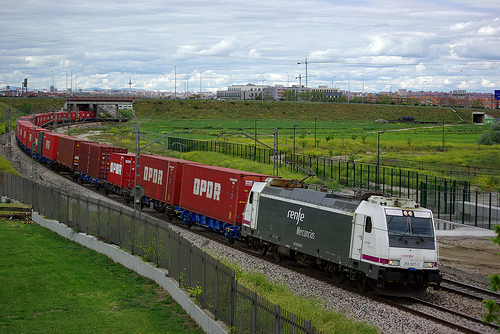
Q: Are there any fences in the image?
A: Yes, there is a fence.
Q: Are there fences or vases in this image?
A: Yes, there is a fence.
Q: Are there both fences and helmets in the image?
A: No, there is a fence but no helmets.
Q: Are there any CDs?
A: No, there are no cds.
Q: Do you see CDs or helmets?
A: No, there are no CDs or helmets.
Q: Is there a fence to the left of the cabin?
A: Yes, there is a fence to the left of the cabin.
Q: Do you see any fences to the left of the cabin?
A: Yes, there is a fence to the left of the cabin.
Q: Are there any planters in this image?
A: No, there are no planters.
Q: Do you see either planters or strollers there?
A: No, there are no planters or strollers.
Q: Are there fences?
A: Yes, there is a fence.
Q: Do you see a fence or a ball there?
A: Yes, there is a fence.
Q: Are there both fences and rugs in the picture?
A: No, there is a fence but no rugs.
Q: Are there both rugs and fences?
A: No, there is a fence but no rugs.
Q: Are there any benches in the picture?
A: No, there are no benches.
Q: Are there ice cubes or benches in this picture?
A: No, there are no benches or ice cubes.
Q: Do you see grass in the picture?
A: Yes, there is grass.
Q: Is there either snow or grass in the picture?
A: Yes, there is grass.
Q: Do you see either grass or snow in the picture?
A: Yes, there is grass.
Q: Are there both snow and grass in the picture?
A: No, there is grass but no snow.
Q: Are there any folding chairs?
A: No, there are no folding chairs.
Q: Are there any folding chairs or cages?
A: No, there are no folding chairs or cages.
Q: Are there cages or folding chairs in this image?
A: No, there are no folding chairs or cages.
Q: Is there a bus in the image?
A: No, there are no buses.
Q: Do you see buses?
A: No, there are no buses.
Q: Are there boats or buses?
A: No, there are no buses or boats.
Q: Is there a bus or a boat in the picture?
A: No, there are no buses or boats.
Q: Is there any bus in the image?
A: No, there are no buses.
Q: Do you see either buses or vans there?
A: No, there are no buses or vans.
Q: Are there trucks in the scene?
A: No, there are no trucks.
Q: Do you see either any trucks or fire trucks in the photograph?
A: No, there are no trucks or fire trucks.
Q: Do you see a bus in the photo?
A: No, there are no buses.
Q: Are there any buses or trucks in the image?
A: No, there are no buses or trucks.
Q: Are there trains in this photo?
A: Yes, there is a train.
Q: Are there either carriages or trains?
A: Yes, there is a train.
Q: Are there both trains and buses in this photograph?
A: No, there is a train but no buses.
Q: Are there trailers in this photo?
A: No, there are no trailers.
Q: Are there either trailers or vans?
A: No, there are no trailers or vans.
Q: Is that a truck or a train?
A: That is a train.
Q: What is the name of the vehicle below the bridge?
A: The vehicle is a train.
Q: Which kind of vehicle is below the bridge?
A: The vehicle is a train.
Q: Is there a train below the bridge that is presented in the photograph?
A: Yes, there is a train below the bridge.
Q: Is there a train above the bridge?
A: No, the train is below the bridge.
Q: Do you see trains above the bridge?
A: No, the train is below the bridge.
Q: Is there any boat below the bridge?
A: No, there is a train below the bridge.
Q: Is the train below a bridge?
A: Yes, the train is below a bridge.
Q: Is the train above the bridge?
A: No, the train is below the bridge.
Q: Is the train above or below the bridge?
A: The train is below the bridge.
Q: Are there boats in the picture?
A: No, there are no boats.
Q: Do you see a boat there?
A: No, there are no boats.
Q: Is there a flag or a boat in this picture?
A: No, there are no boats or flags.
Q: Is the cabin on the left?
A: No, the cabin is on the right of the image.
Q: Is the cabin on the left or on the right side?
A: The cabin is on the right of the image.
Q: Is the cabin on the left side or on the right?
A: The cabin is on the right of the image.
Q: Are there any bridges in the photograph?
A: Yes, there is a bridge.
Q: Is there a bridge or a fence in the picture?
A: Yes, there is a bridge.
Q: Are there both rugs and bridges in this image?
A: No, there is a bridge but no rugs.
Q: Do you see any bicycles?
A: No, there are no bicycles.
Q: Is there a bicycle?
A: No, there are no bicycles.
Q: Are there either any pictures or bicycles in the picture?
A: No, there are no bicycles or pictures.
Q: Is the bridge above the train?
A: Yes, the bridge is above the train.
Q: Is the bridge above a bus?
A: No, the bridge is above the train.